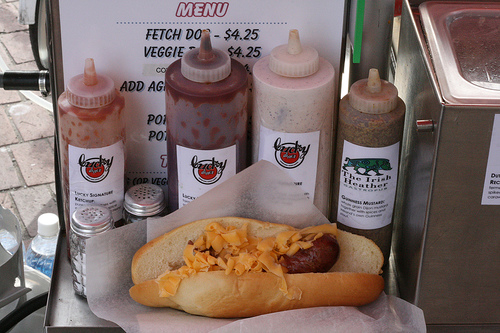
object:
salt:
[67, 205, 116, 299]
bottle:
[24, 213, 61, 283]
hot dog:
[276, 233, 340, 274]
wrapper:
[84, 219, 147, 333]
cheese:
[153, 222, 340, 301]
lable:
[175, 144, 239, 210]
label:
[337, 139, 401, 230]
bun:
[128, 216, 384, 318]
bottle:
[330, 68, 406, 267]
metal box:
[393, 0, 500, 333]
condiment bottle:
[251, 29, 335, 220]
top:
[37, 212, 59, 235]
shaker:
[68, 205, 116, 298]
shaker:
[123, 183, 168, 225]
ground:
[426, 323, 499, 333]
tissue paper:
[86, 159, 427, 333]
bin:
[389, 0, 500, 333]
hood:
[57, 58, 125, 228]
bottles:
[164, 29, 248, 213]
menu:
[118, 1, 288, 187]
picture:
[0, 0, 500, 333]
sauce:
[164, 29, 249, 211]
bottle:
[57, 58, 126, 228]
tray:
[41, 228, 122, 333]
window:
[0, 0, 64, 279]